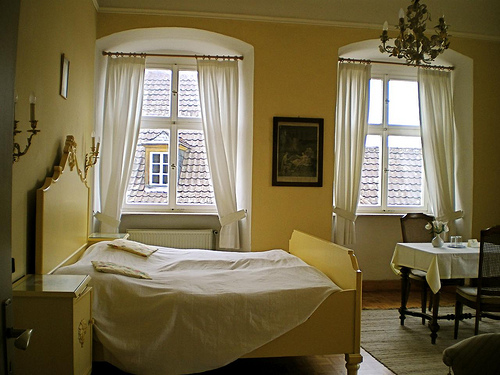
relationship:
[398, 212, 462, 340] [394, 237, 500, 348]
chair by table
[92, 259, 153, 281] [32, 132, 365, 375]
pillow on bed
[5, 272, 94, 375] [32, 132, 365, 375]
end table by bed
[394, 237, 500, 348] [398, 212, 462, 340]
table and chair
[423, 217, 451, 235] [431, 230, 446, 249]
flowers in vase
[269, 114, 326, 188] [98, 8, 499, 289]
painting on wall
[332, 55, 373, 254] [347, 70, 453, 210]
curtain on window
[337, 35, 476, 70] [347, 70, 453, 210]
moulding over window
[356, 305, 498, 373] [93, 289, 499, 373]
rug on floor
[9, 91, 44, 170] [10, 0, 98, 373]
sconse on wall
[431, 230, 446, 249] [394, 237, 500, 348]
vase on table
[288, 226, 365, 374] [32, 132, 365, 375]
footboard on bed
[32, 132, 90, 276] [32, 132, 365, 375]
headboard on bed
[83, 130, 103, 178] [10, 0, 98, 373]
sconce on wall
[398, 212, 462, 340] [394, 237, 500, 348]
chair at table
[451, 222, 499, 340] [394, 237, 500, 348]
chair at table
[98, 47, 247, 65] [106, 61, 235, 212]
rod on window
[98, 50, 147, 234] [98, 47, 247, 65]
drape on rod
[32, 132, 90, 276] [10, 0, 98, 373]
headboard against wall